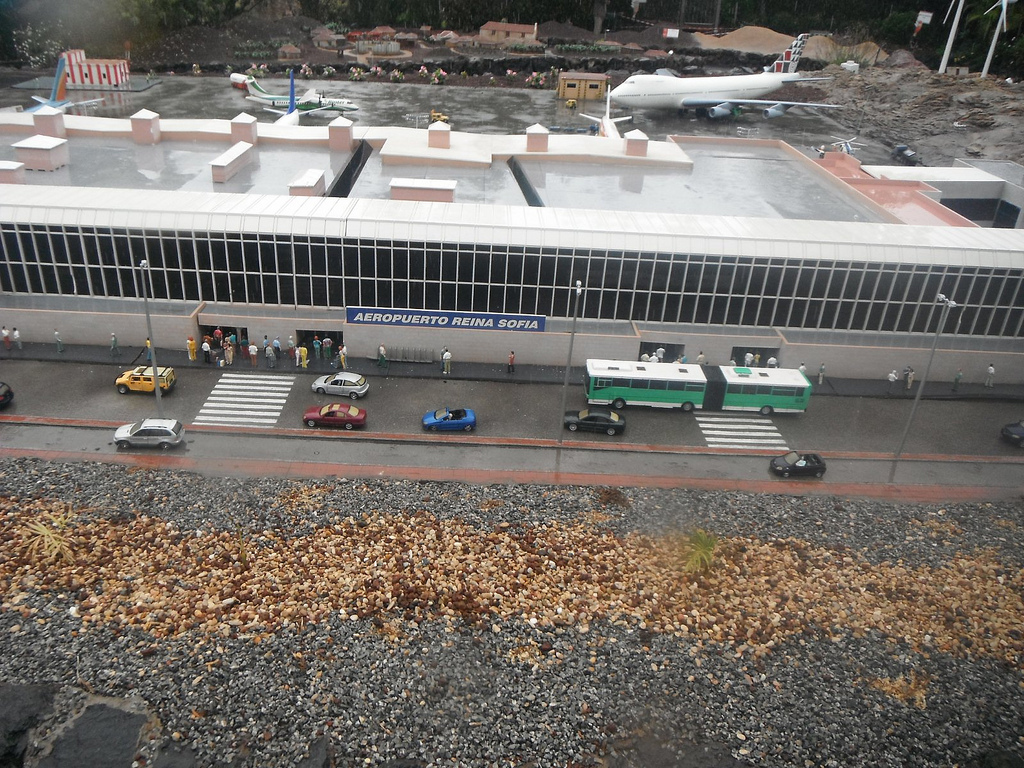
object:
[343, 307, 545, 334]
sign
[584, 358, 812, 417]
bus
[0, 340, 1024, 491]
road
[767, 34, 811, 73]
tail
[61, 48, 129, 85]
building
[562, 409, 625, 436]
car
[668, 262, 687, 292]
window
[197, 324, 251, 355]
entrance way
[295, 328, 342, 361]
entrance way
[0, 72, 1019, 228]
airport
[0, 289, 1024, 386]
wall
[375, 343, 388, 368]
people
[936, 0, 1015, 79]
turbines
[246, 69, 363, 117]
airplane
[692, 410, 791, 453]
lines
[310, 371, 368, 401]
car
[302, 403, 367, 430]
car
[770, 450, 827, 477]
car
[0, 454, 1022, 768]
rocks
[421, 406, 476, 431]
car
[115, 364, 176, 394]
car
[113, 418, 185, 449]
car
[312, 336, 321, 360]
people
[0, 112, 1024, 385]
building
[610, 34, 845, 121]
airplane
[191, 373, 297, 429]
crosswalk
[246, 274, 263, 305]
windows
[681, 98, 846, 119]
wing